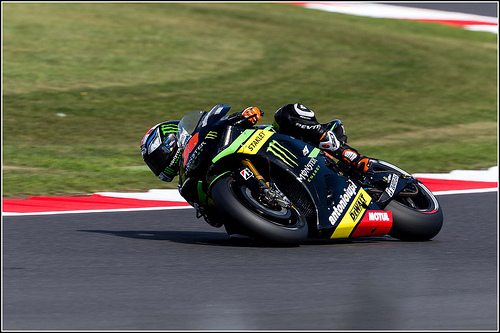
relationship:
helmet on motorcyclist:
[140, 112, 193, 182] [137, 64, 343, 188]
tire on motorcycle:
[208, 176, 304, 247] [100, 95, 494, 257]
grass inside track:
[3, 1, 498, 197] [2, 205, 182, 322]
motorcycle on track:
[100, 95, 494, 257] [2, 205, 182, 322]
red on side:
[9, 194, 102, 222] [5, 187, 126, 252]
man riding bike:
[138, 104, 418, 204] [100, 95, 494, 257]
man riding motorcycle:
[130, 80, 270, 178] [100, 95, 494, 257]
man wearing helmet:
[130, 80, 270, 178] [140, 112, 193, 182]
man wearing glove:
[130, 80, 270, 178] [240, 101, 261, 130]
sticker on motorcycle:
[214, 125, 251, 156] [100, 95, 494, 257]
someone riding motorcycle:
[130, 80, 270, 178] [100, 95, 494, 257]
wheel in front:
[208, 176, 304, 247] [197, 131, 312, 269]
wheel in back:
[373, 156, 445, 243] [346, 108, 444, 238]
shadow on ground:
[71, 221, 202, 253] [49, 218, 193, 311]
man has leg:
[138, 104, 418, 204] [284, 99, 374, 190]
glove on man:
[240, 101, 261, 130] [138, 104, 418, 204]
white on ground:
[123, 190, 178, 205] [49, 218, 193, 311]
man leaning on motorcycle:
[138, 104, 418, 204] [100, 95, 494, 257]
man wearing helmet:
[138, 104, 418, 204] [140, 112, 193, 182]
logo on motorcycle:
[264, 135, 306, 168] [100, 95, 494, 257]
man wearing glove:
[138, 104, 418, 204] [237, 106, 261, 125]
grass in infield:
[3, 1, 498, 197] [91, 19, 376, 96]